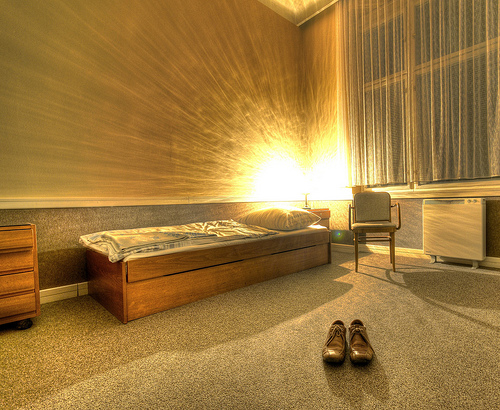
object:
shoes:
[320, 318, 380, 370]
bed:
[80, 206, 332, 324]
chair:
[346, 185, 403, 276]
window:
[342, 0, 499, 193]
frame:
[76, 222, 334, 321]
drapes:
[337, 0, 500, 188]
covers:
[79, 218, 327, 265]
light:
[264, 148, 349, 205]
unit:
[421, 195, 490, 271]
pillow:
[237, 204, 322, 232]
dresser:
[0, 220, 42, 334]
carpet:
[1, 324, 318, 407]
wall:
[309, 0, 500, 267]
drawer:
[125, 215, 335, 263]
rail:
[0, 194, 309, 208]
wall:
[0, 0, 304, 313]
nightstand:
[305, 207, 333, 228]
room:
[0, 0, 499, 409]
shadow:
[4, 257, 354, 409]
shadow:
[357, 258, 500, 321]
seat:
[350, 190, 398, 233]